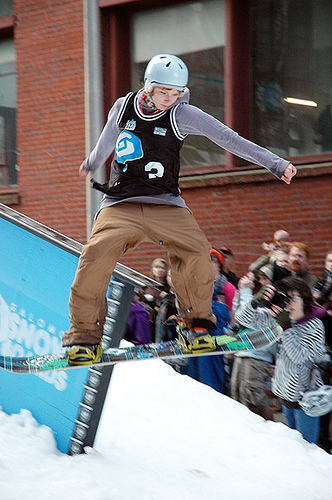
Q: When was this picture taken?
A: Daytime.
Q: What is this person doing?
A: Snowboarding.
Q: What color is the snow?
A: White.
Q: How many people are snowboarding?
A: One.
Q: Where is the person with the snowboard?
A: In the air.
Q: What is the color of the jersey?
A: Black.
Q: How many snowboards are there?
A: One.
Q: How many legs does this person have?
A: Two.